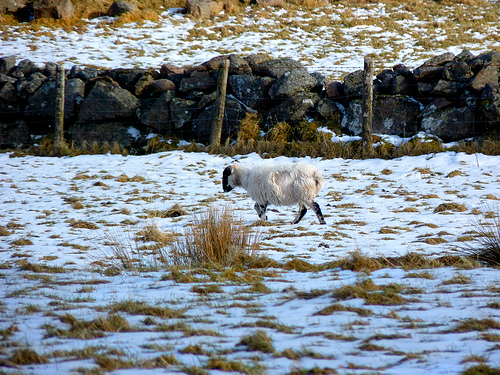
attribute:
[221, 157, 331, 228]
sheep — white, walking, standing, black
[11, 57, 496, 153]
wall — stone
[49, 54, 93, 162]
fence — wooden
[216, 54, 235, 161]
post — wooden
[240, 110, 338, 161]
bush — brown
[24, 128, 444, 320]
field — snowy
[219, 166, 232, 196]
face — black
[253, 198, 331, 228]
legs — black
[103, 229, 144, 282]
grass — brown, green, tall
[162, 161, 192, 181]
snow — white, brown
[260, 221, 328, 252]
ground — covered, patchy, green, white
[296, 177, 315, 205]
fur — white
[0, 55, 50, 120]
rocks — gray